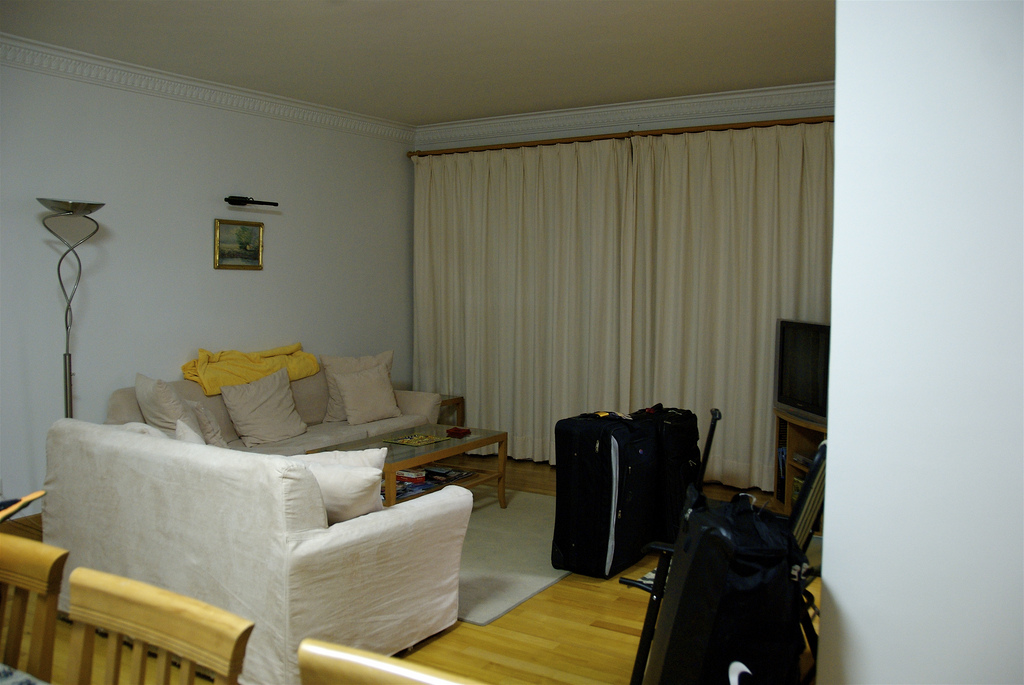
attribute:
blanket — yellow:
[174, 340, 331, 398]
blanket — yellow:
[182, 343, 326, 392]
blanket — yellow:
[183, 347, 323, 395]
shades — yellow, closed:
[411, 118, 830, 492]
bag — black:
[552, 409, 655, 580]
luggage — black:
[631, 493, 816, 681]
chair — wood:
[59, 567, 253, 681]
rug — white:
[441, 489, 577, 623]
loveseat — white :
[43, 414, 473, 680]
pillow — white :
[266, 441, 384, 518]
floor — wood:
[394, 480, 822, 680]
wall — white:
[3, 34, 415, 513]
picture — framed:
[212, 216, 264, 273]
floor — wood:
[394, 453, 818, 682]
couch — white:
[109, 353, 442, 462]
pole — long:
[49, 204, 86, 419]